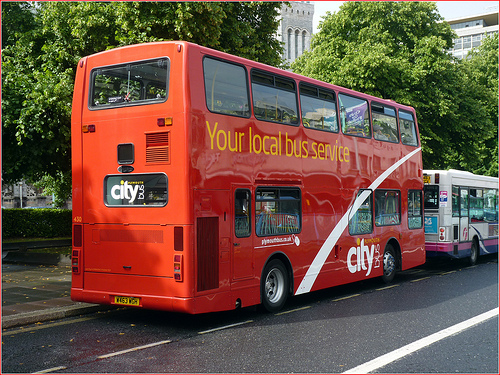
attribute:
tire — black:
[264, 255, 300, 310]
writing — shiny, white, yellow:
[207, 93, 368, 169]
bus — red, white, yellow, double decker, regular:
[50, 18, 452, 323]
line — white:
[354, 277, 476, 374]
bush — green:
[4, 122, 72, 240]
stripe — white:
[263, 143, 436, 289]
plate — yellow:
[87, 285, 153, 311]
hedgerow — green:
[442, 11, 488, 31]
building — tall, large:
[271, 5, 319, 76]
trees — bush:
[10, 52, 73, 180]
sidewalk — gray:
[3, 251, 417, 333]